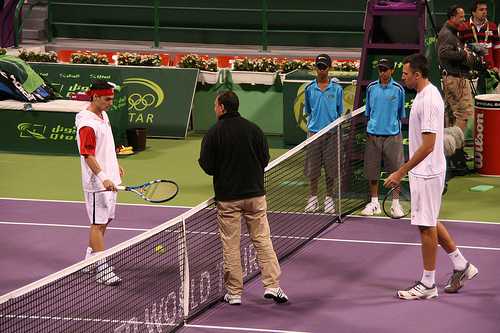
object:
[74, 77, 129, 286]
man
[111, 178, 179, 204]
tennis racket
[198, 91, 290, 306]
man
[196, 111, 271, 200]
jacket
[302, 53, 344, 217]
man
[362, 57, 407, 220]
man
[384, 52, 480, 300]
player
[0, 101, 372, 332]
net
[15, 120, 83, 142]
logo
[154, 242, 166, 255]
ball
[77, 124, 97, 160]
sleeve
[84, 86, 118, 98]
headband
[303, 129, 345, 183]
shorts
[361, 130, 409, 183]
shorts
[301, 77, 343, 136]
shirt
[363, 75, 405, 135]
shirt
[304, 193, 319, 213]
shoe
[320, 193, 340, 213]
shoe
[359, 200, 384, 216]
shoe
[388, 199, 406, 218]
shoe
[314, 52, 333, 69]
cap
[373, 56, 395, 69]
cap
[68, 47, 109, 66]
flowers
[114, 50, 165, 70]
flowers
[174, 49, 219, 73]
flowers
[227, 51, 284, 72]
flowers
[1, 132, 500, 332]
tennis court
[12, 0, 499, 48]
railing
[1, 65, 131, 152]
table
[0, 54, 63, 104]
bag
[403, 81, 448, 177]
shirt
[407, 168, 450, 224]
shorts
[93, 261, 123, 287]
shoe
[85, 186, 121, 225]
shorts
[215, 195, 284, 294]
pants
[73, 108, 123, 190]
vest